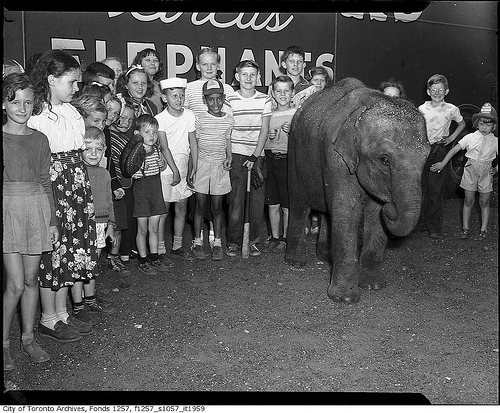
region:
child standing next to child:
[3, 73, 61, 373]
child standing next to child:
[22, 49, 102, 342]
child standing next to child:
[78, 123, 111, 284]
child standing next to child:
[279, 46, 310, 95]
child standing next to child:
[155, 80, 200, 255]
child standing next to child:
[190, 70, 221, 255]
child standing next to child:
[225, 60, 270, 255]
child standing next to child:
[265, 77, 296, 250]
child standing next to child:
[429, 100, 497, 242]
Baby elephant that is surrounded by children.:
[276, 79, 433, 312]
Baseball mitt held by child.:
[119, 136, 149, 176]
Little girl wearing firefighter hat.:
[428, 97, 498, 247]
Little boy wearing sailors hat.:
[147, 74, 189, 268]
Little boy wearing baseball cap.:
[192, 79, 232, 268]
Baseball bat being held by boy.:
[233, 154, 256, 265]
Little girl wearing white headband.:
[118, 61, 165, 118]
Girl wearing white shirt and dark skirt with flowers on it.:
[25, 47, 97, 349]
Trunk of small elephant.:
[381, 179, 422, 238]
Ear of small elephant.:
[328, 115, 370, 175]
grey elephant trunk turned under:
[377, 197, 417, 236]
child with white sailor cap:
[165, 80, 197, 114]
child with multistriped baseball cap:
[198, 82, 240, 145]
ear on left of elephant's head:
[331, 104, 374, 191]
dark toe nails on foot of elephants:
[320, 288, 377, 317]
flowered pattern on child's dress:
[69, 194, 99, 259]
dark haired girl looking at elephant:
[41, 54, 88, 101]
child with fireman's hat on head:
[474, 93, 494, 138]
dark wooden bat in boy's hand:
[241, 148, 258, 305]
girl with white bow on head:
[118, 56, 146, 80]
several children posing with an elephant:
[1, 47, 498, 367]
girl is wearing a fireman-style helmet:
[472, 101, 497, 133]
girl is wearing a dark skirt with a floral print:
[38, 148, 100, 290]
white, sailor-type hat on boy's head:
[157, 76, 188, 111]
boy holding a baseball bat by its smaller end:
[240, 153, 256, 260]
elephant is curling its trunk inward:
[355, 98, 430, 237]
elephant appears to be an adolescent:
[283, 77, 430, 305]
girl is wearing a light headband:
[117, 63, 154, 101]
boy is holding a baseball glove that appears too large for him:
[110, 100, 146, 180]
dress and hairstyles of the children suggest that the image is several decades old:
[2, 45, 499, 371]